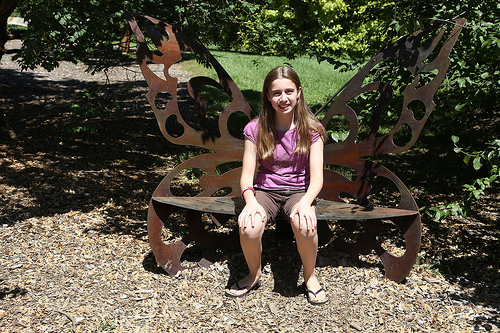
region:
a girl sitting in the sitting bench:
[240, 67, 351, 319]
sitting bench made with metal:
[126, 153, 424, 288]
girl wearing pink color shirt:
[241, 115, 320, 195]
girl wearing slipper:
[221, 273, 328, 305]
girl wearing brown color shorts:
[239, 186, 310, 222]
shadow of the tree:
[27, 82, 129, 202]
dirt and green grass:
[221, 45, 328, 70]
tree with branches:
[6, 5, 98, 62]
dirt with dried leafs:
[32, 233, 114, 318]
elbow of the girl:
[300, 168, 333, 192]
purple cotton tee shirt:
[243, 117, 317, 186]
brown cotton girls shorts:
[251, 186, 311, 221]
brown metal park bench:
[128, 3, 462, 282]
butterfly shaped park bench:
[126, 8, 464, 285]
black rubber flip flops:
[222, 271, 331, 304]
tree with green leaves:
[2, 1, 267, 68]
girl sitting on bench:
[228, 66, 329, 303]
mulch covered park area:
[2, 19, 483, 330]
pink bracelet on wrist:
[240, 185, 256, 200]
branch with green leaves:
[429, 163, 499, 225]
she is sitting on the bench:
[137, 27, 430, 299]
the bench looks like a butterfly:
[118, 15, 463, 286]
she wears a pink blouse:
[242, 120, 324, 192]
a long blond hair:
[252, 69, 314, 159]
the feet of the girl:
[226, 276, 323, 306]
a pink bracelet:
[242, 186, 251, 192]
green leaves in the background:
[205, 8, 432, 41]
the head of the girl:
[262, 67, 299, 115]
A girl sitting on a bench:
[115, 3, 475, 309]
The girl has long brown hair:
[246, 57, 327, 178]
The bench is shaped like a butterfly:
[115, 5, 475, 295]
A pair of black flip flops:
[217, 267, 332, 307]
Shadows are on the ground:
[0, 57, 495, 327]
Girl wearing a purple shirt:
[236, 60, 327, 192]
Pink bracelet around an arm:
[232, 180, 258, 200]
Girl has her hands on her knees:
[230, 60, 330, 240]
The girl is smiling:
[255, 62, 310, 124]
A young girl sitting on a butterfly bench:
[98, 8, 463, 306]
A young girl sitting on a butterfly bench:
[105, 3, 469, 308]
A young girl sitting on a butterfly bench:
[101, 5, 481, 310]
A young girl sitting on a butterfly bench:
[105, 3, 477, 315]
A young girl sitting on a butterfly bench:
[114, 6, 465, 308]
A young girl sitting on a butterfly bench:
[114, 8, 474, 313]